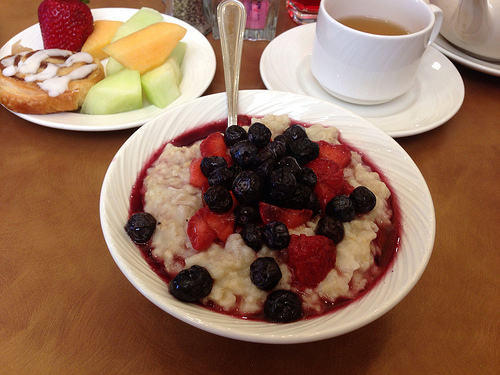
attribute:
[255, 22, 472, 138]
plate — white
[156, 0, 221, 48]
shaker — pepper shaker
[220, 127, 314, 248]
fruit — top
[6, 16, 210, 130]
plate — small, white, round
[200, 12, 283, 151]
spoon — silver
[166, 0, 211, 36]
shaker — glass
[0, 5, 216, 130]
plate — small, white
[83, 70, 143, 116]
cantaloupe — slices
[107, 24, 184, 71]
melon — slices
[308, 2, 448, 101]
cup — white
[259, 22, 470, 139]
saucer — white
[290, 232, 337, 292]
strawberry — red, one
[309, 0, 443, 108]
cup — white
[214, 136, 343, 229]
fruit — top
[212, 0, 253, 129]
handle — silver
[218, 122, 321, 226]
blueberries — pile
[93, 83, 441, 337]
bowl — white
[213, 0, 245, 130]
handle — silver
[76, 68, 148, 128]
melon — slice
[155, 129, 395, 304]
oatmeal —  with blackberries,  with blueberries,  with  strawberries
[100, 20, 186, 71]
cantaloupe —  a piece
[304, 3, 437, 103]
mug —  white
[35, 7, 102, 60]
strawberry — big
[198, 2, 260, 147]
flat ware — silver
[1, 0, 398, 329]
breakfast —  fruit,  danish,  oatmeal